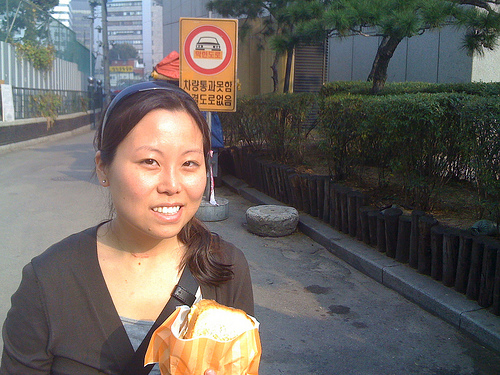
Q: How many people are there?
A: 1.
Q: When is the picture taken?
A: Daytime.